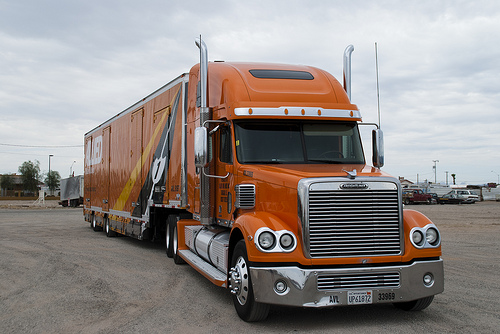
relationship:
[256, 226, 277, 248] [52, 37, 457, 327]
headlight on truck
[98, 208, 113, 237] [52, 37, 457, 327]
wheel of truck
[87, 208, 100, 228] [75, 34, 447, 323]
wheel of truck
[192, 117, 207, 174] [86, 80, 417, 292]
chrome mirror of truck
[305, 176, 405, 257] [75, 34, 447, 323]
grill of truck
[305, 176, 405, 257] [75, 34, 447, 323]
grill on truck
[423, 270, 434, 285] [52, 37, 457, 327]
foglight on a truck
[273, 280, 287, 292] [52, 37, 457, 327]
foglight on a truck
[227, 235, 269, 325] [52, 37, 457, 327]
black tire on a truck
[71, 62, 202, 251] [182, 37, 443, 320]
trailer on a semi truck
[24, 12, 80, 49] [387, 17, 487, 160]
clouds in sky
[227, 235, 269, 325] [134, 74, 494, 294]
black tire on truck